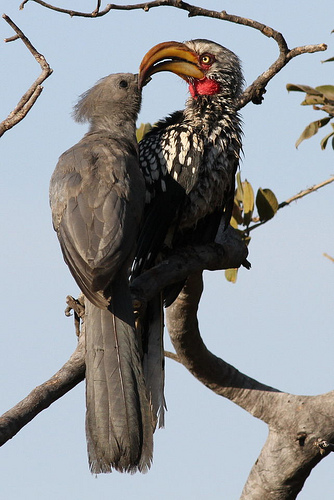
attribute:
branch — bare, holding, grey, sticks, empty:
[187, 336, 314, 464]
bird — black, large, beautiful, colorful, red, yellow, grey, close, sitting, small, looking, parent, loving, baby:
[159, 38, 251, 237]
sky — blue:
[38, 23, 117, 74]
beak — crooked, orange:
[135, 41, 203, 87]